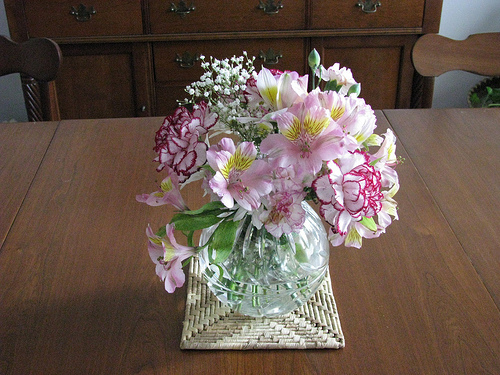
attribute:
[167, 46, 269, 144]
babys breath — little, white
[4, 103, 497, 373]
dining table — brown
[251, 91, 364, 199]
flowers — pink, yellow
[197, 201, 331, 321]
vase — short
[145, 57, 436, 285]
flowers — bouquet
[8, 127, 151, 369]
table — large, wood, dining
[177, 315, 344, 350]
mat — brown, place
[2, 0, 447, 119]
cabinet — brown, wooden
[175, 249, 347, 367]
mat — white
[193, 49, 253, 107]
flowers — baby's breath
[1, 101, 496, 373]
table — wooden, dining, brown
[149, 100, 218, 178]
flower — white, purple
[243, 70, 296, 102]
flower — purple, white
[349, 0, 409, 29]
drawer — brown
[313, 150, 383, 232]
flower — purple, white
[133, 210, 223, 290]
flower — pink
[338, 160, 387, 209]
tips — red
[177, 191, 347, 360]
vase — crystal